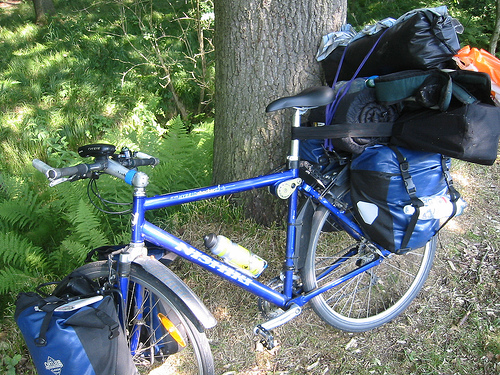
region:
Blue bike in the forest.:
[28, 75, 466, 371]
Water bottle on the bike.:
[201, 225, 270, 276]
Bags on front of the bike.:
[10, 241, 197, 373]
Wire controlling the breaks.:
[83, 173, 140, 248]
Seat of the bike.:
[261, 83, 333, 117]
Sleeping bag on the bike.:
[328, 85, 405, 152]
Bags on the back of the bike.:
[292, 134, 467, 255]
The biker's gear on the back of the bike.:
[313, 5, 495, 170]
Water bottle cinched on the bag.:
[402, 193, 466, 226]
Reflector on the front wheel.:
[148, 310, 188, 347]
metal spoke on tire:
[313, 249, 366, 260]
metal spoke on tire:
[319, 229, 362, 254]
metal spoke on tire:
[324, 278, 353, 303]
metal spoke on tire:
[332, 286, 347, 309]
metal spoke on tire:
[348, 273, 360, 314]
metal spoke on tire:
[367, 268, 376, 317]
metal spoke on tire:
[130, 290, 151, 327]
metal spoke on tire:
[134, 299, 158, 340]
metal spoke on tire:
[139, 322, 182, 351]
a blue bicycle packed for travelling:
[9, 12, 486, 372]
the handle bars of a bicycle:
[26, 143, 166, 186]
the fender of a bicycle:
[110, 247, 233, 332]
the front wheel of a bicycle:
[65, 260, 212, 374]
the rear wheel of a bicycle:
[276, 180, 446, 328]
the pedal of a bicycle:
[238, 306, 285, 353]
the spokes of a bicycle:
[328, 278, 398, 311]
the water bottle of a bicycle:
[198, 232, 274, 276]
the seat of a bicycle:
[260, 83, 337, 116]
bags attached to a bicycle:
[302, 8, 498, 258]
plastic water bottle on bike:
[186, 231, 281, 283]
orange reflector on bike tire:
[154, 309, 186, 351]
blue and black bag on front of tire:
[1, 293, 191, 373]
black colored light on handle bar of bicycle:
[68, 128, 137, 170]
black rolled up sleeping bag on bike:
[331, 80, 394, 142]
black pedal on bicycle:
[253, 318, 285, 360]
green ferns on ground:
[7, 192, 96, 242]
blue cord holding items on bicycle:
[326, 41, 386, 98]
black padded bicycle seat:
[263, 75, 337, 127]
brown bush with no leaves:
[140, 19, 202, 86]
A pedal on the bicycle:
[252, 325, 282, 355]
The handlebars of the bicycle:
[30, 148, 159, 185]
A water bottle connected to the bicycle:
[206, 228, 267, 279]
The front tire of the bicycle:
[57, 264, 214, 374]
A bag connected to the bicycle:
[349, 144, 460, 256]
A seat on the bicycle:
[267, 85, 334, 115]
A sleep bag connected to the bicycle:
[333, 93, 393, 152]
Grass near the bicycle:
[0, 0, 492, 373]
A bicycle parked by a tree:
[16, 9, 497, 374]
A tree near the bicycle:
[211, 0, 348, 230]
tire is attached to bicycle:
[302, 177, 439, 329]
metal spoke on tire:
[356, 282, 367, 317]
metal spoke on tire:
[335, 280, 350, 312]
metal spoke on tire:
[384, 261, 413, 276]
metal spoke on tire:
[402, 255, 424, 272]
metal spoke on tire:
[315, 247, 375, 271]